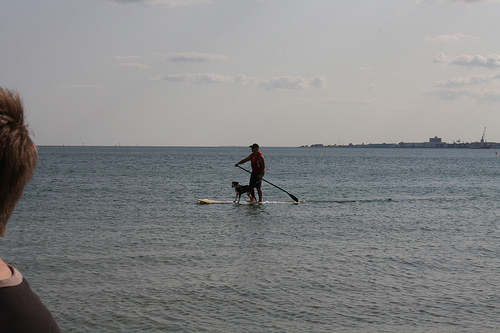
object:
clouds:
[137, 73, 326, 92]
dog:
[230, 180, 259, 202]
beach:
[0, 145, 499, 333]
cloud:
[153, 50, 231, 63]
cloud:
[259, 76, 325, 91]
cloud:
[142, 73, 224, 87]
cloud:
[429, 53, 499, 73]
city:
[296, 127, 499, 151]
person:
[233, 143, 266, 203]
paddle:
[233, 163, 301, 203]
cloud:
[415, 74, 499, 109]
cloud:
[120, 61, 158, 73]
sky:
[0, 0, 499, 148]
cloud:
[157, 49, 226, 62]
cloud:
[433, 71, 500, 86]